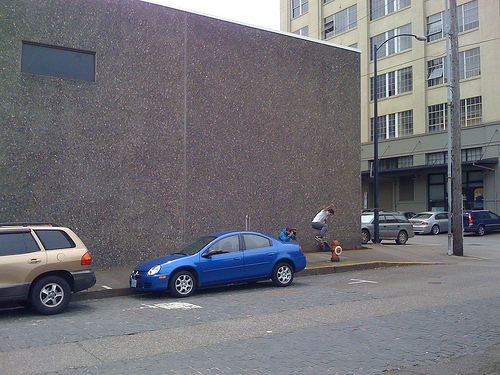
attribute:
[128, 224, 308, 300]
car — blue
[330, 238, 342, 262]
hydrant — orange, white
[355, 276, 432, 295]
asphalt — dry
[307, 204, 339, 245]
person — skateboarder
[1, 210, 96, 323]
suv — gold, tan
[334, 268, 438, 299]
street — paved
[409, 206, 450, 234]
car — silver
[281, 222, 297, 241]
person — crouching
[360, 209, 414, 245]
car — green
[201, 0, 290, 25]
sky — cloudy